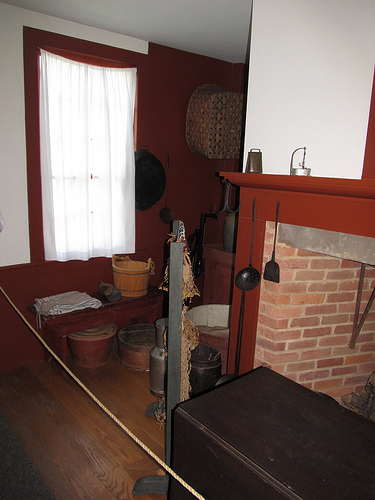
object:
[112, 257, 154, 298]
basket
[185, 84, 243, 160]
wicker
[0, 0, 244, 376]
wall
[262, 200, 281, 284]
shovel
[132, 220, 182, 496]
pole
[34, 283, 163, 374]
bench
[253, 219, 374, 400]
fireplace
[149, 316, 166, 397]
jug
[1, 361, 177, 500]
floor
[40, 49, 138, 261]
cloth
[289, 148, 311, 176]
cow bell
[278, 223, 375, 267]
mantle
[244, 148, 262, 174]
oil canter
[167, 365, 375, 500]
hope chest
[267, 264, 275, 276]
iron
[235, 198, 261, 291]
fire scoop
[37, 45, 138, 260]
curtains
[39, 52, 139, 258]
window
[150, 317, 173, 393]
churn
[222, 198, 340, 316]
utensisl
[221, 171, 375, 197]
grater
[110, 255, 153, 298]
bucket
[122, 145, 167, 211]
pan